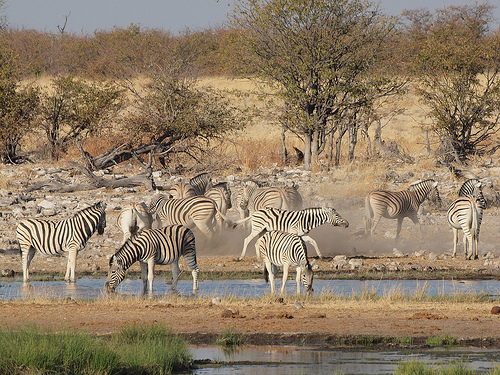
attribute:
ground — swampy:
[207, 339, 373, 371]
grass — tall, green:
[1, 321, 208, 372]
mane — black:
[292, 234, 317, 264]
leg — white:
[141, 254, 167, 296]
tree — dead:
[25, 141, 182, 210]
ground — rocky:
[143, 156, 330, 204]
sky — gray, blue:
[6, 2, 316, 51]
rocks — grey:
[33, 194, 96, 221]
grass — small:
[387, 330, 477, 350]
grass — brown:
[232, 128, 278, 178]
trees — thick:
[53, 25, 226, 95]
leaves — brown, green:
[132, 27, 178, 84]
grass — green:
[74, 313, 184, 373]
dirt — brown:
[339, 309, 392, 332]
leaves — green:
[113, 104, 169, 116]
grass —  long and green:
[8, 321, 183, 375]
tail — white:
[352, 192, 382, 231]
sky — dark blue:
[24, 50, 167, 54]